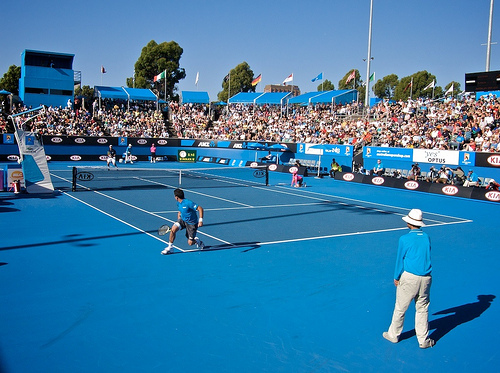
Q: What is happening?
A: Tennis tournament.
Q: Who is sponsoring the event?
A: KIA.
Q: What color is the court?
A: Blue.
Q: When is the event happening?
A: Daytime.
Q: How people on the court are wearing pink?
A: 2.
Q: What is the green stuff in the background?
A: Trees.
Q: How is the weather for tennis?
A: Sunny.